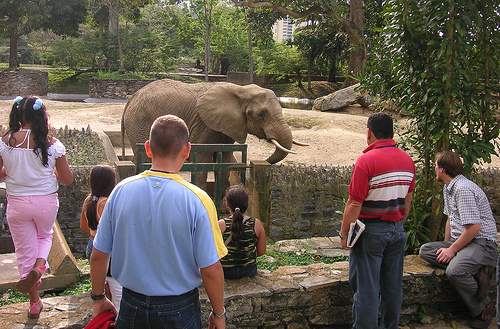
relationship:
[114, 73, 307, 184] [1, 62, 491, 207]
elephant on enclosure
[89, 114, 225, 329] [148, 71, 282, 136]
child on elephant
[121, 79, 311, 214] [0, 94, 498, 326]
elephant on ground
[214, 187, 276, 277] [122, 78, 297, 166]
child on elephant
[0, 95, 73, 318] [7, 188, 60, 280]
child on pants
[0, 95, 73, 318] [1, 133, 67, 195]
child on blouse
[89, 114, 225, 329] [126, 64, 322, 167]
child on elephant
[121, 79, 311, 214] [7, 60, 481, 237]
elephant in habitat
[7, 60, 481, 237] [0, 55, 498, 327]
habitat at zoo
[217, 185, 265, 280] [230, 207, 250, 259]
child with hair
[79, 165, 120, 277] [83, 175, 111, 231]
child with hair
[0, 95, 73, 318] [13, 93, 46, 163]
child with hair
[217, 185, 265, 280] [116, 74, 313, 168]
child watches elephant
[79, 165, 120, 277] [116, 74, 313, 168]
child watches elephant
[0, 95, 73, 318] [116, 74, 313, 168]
child watches elephant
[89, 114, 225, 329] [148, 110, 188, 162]
child has buzz cut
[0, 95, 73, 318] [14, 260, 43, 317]
child standing on foot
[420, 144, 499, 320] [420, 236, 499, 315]
gentleman wearing ensemble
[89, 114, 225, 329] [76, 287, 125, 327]
child carrying backpack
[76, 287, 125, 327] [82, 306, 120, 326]
backpack with straps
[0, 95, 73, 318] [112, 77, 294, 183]
child watching elephant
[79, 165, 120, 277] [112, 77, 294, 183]
child watching elephant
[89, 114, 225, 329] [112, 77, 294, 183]
child watching elephant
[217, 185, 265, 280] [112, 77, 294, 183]
child watching elephant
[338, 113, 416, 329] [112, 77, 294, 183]
man watching elephant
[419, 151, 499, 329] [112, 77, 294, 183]
gentleman watching elephant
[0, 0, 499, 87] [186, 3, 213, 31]
trees with branch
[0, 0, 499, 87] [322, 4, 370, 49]
trees with branch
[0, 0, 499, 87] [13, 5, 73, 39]
trees with branch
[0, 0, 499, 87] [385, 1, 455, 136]
trees with branch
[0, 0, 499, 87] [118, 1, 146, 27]
trees with branch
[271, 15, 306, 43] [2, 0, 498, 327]
building near zoo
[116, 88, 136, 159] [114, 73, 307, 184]
tail of elephant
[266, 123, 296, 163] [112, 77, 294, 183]
trunk of elephant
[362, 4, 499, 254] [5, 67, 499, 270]
tree near enclosure